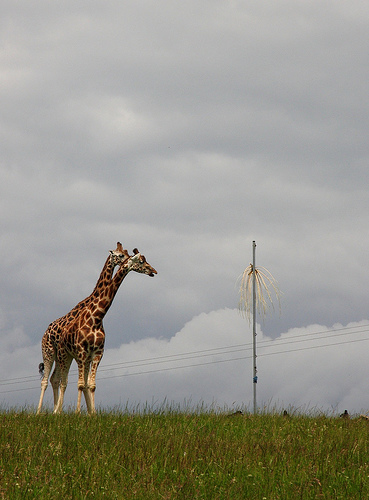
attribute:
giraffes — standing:
[33, 244, 188, 411]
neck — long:
[75, 263, 127, 307]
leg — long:
[75, 355, 89, 408]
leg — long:
[33, 354, 52, 409]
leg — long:
[85, 364, 99, 415]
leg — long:
[55, 360, 63, 411]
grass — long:
[145, 413, 271, 497]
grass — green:
[140, 411, 242, 497]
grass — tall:
[3, 413, 367, 459]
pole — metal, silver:
[248, 236, 260, 410]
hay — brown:
[241, 265, 277, 315]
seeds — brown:
[52, 452, 66, 460]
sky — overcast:
[69, 81, 270, 193]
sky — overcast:
[50, 76, 209, 137]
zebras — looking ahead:
[32, 237, 158, 418]